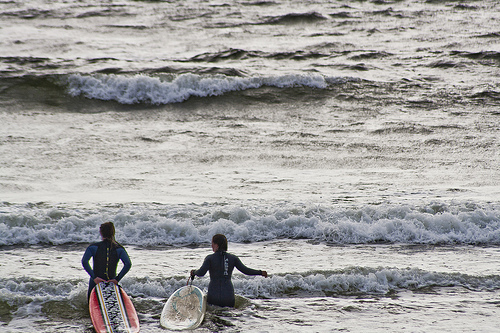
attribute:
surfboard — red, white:
[86, 272, 137, 328]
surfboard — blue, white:
[160, 285, 204, 331]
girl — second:
[187, 232, 268, 309]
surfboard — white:
[162, 285, 209, 330]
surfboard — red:
[87, 283, 139, 331]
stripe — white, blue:
[98, 280, 129, 330]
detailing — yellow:
[102, 243, 111, 280]